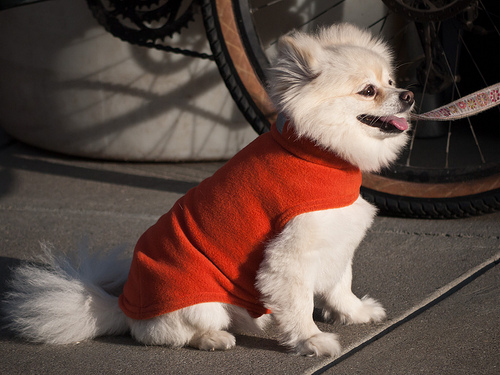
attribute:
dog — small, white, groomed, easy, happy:
[13, 26, 417, 351]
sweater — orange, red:
[124, 130, 357, 315]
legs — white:
[266, 227, 380, 358]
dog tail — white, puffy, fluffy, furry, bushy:
[6, 255, 123, 350]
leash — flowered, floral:
[403, 87, 499, 137]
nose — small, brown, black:
[396, 90, 415, 106]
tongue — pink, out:
[380, 112, 409, 134]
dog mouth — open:
[353, 103, 413, 150]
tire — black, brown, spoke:
[201, 12, 498, 195]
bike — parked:
[100, 7, 499, 215]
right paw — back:
[188, 328, 243, 360]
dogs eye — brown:
[355, 77, 379, 103]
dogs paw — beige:
[198, 331, 344, 359]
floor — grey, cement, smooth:
[5, 159, 484, 373]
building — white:
[7, 15, 376, 155]